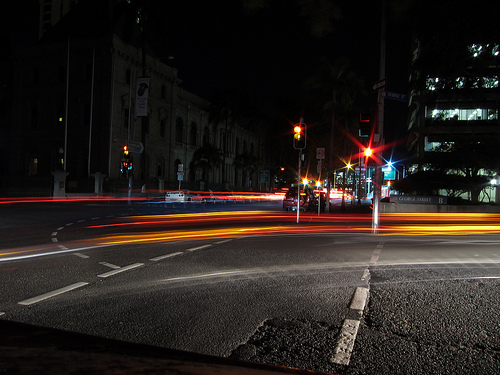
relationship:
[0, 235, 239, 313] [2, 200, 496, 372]
line on street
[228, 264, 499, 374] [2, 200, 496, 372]
patched pavement in street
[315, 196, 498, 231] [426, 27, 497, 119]
sidewalk in front of building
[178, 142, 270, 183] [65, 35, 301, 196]
trees in front of building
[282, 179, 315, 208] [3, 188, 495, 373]
car parked on road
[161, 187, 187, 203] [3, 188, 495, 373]
car parked on road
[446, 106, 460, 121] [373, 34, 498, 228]
light on building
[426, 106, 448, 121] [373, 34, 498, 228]
light on building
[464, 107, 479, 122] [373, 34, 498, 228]
light on building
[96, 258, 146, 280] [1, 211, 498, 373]
marking on road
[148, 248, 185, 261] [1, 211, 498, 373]
marking on road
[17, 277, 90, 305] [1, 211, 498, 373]
marking on road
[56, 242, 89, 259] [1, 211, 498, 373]
marking on road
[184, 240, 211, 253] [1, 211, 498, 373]
marking on road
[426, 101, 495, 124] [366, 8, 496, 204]
window on building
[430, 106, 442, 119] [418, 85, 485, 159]
glass window on building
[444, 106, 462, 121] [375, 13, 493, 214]
window on building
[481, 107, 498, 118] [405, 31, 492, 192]
window on building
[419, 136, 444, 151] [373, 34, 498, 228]
window on building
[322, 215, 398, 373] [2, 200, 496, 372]
line on street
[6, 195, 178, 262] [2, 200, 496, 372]
line on street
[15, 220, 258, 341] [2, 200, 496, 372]
line on street